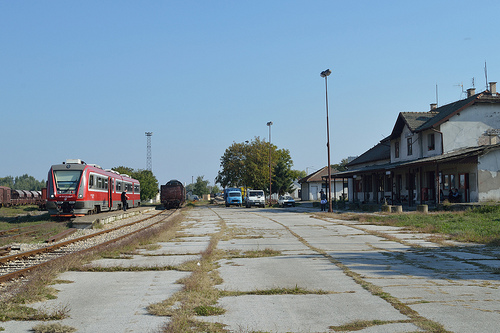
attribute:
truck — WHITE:
[246, 190, 266, 209]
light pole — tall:
[318, 60, 335, 219]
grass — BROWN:
[3, 199, 499, 331]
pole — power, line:
[140, 129, 162, 173]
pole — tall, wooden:
[315, 59, 342, 212]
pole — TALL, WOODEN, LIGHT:
[259, 117, 278, 224]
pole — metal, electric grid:
[142, 129, 155, 186]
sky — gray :
[163, 59, 237, 115]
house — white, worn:
[327, 82, 498, 209]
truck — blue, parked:
[221, 184, 246, 208]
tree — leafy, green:
[189, 126, 313, 183]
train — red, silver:
[40, 150, 150, 227]